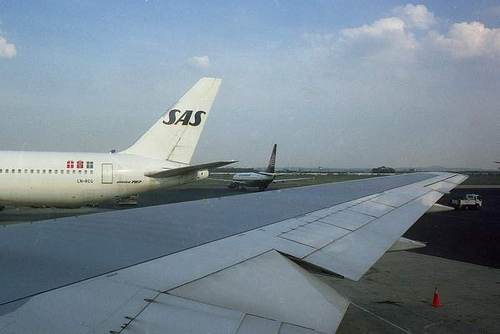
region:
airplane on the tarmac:
[206, 147, 318, 187]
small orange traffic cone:
[420, 282, 445, 306]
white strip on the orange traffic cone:
[431, 284, 443, 295]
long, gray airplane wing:
[1, 159, 466, 331]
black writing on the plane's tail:
[157, 101, 207, 132]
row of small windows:
[1, 165, 98, 175]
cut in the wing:
[276, 243, 376, 310]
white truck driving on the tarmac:
[448, 189, 488, 212]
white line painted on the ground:
[348, 295, 404, 332]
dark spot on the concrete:
[376, 296, 403, 308]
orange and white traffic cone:
[428, 284, 447, 307]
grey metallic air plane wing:
[2, 166, 472, 330]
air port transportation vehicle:
[444, 191, 487, 217]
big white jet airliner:
[7, 73, 241, 219]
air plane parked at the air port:
[215, 139, 292, 201]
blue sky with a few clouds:
[1, 1, 498, 178]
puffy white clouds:
[322, 3, 498, 73]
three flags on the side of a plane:
[58, 156, 98, 171]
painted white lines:
[330, 290, 415, 331]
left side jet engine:
[221, 179, 238, 190]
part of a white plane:
[0, 69, 243, 207]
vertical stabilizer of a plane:
[128, 71, 232, 158]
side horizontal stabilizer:
[142, 145, 238, 188]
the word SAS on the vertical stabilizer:
[140, 67, 230, 156]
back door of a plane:
[97, 152, 118, 189]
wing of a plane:
[5, 163, 480, 322]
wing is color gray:
[0, 167, 487, 332]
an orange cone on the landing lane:
[423, 280, 448, 314]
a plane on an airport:
[213, 135, 297, 197]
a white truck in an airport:
[442, 184, 489, 215]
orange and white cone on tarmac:
[425, 277, 446, 309]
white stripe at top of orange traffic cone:
[427, 283, 444, 297]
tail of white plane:
[148, 66, 230, 161]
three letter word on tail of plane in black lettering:
[161, 105, 211, 132]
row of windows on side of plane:
[2, 161, 100, 180]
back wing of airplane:
[142, 152, 252, 184]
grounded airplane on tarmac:
[216, 136, 321, 194]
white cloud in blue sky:
[335, 19, 442, 86]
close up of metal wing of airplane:
[3, 151, 485, 326]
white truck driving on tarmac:
[446, 186, 487, 211]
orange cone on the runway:
[425, 280, 448, 327]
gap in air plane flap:
[273, 220, 365, 332]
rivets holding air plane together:
[245, 185, 390, 246]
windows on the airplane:
[4, 159, 109, 179]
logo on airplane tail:
[163, 98, 212, 137]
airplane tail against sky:
[131, 68, 243, 176]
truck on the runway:
[447, 190, 491, 214]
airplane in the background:
[217, 132, 291, 207]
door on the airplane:
[92, 158, 121, 192]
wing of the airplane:
[90, 157, 477, 332]